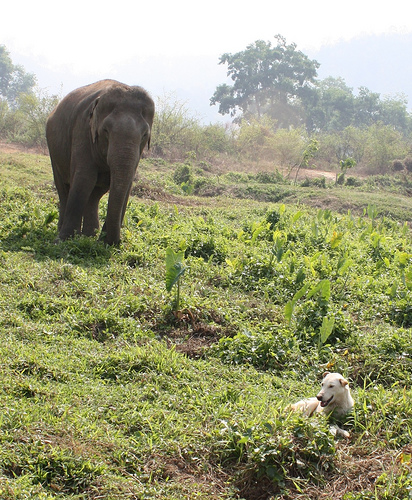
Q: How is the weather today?
A: It is overcast.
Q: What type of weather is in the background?
A: It is overcast.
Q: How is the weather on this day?
A: It is overcast.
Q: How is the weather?
A: It is overcast.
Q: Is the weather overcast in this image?
A: Yes, it is overcast.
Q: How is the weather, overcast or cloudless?
A: It is overcast.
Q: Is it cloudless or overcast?
A: It is overcast.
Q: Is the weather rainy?
A: No, it is overcast.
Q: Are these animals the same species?
A: No, they are dogs and elephants.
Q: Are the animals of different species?
A: Yes, they are dogs and elephants.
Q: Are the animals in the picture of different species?
A: Yes, they are dogs and elephants.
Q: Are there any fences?
A: No, there are no fences.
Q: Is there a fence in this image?
A: No, there are no fences.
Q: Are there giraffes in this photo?
A: No, there are no giraffes.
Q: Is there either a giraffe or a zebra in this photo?
A: No, there are no giraffes or zebras.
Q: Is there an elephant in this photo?
A: Yes, there is an elephant.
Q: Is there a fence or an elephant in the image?
A: Yes, there is an elephant.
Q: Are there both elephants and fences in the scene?
A: No, there is an elephant but no fences.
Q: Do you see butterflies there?
A: No, there are no butterflies.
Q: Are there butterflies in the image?
A: No, there are no butterflies.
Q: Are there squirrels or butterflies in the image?
A: No, there are no butterflies or squirrels.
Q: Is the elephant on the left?
A: Yes, the elephant is on the left of the image.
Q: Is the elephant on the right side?
A: No, the elephant is on the left of the image.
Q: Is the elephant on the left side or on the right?
A: The elephant is on the left of the image.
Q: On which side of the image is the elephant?
A: The elephant is on the left of the image.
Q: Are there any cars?
A: No, there are no cars.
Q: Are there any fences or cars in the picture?
A: No, there are no cars or fences.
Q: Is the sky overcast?
A: Yes, the sky is overcast.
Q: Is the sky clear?
A: No, the sky is overcast.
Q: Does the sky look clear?
A: No, the sky is overcast.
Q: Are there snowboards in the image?
A: No, there are no snowboards.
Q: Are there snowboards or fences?
A: No, there are no snowboards or fences.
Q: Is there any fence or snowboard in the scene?
A: No, there are no snowboards or fences.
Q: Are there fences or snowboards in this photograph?
A: No, there are no snowboards or fences.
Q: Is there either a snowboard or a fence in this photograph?
A: No, there are no snowboards or fences.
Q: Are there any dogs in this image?
A: Yes, there is a dog.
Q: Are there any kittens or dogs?
A: Yes, there is a dog.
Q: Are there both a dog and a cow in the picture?
A: No, there is a dog but no cows.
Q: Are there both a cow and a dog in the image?
A: No, there is a dog but no cows.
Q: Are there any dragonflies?
A: No, there are no dragonflies.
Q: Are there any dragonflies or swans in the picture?
A: No, there are no dragonflies or swans.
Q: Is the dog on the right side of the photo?
A: Yes, the dog is on the right of the image.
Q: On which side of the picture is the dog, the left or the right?
A: The dog is on the right of the image.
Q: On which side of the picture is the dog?
A: The dog is on the right of the image.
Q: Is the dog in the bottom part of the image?
A: Yes, the dog is in the bottom of the image.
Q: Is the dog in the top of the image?
A: No, the dog is in the bottom of the image.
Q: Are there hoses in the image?
A: No, there are no hoses.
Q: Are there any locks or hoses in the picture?
A: No, there are no hoses or locks.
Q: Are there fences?
A: No, there are no fences.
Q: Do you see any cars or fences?
A: No, there are no fences or cars.